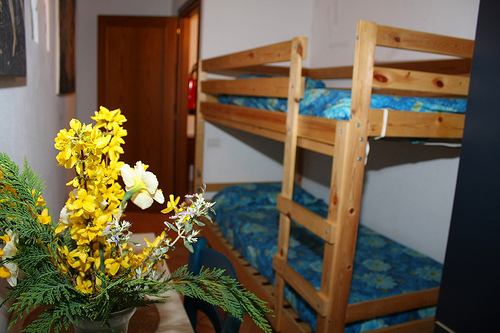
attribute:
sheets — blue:
[214, 182, 451, 322]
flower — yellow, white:
[1, 103, 276, 332]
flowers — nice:
[32, 105, 155, 279]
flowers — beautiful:
[0, 100, 274, 332]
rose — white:
[118, 157, 165, 212]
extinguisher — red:
[189, 76, 195, 113]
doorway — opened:
[177, 4, 197, 189]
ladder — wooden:
[266, 20, 361, 330]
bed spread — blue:
[182, 178, 441, 331]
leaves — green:
[168, 270, 240, 299]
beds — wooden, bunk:
[197, 33, 445, 323]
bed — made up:
[201, 179, 456, 329]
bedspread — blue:
[212, 185, 444, 330]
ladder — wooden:
[277, 114, 357, 329]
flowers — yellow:
[37, 101, 172, 288]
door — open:
[92, 11, 179, 216]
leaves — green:
[168, 222, 255, 308]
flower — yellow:
[41, 109, 146, 299]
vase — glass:
[62, 298, 148, 329]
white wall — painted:
[0, 1, 479, 263]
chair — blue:
[174, 232, 250, 332]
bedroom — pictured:
[112, 13, 445, 330]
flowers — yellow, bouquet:
[32, 103, 182, 315]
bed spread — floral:
[206, 181, 443, 325]